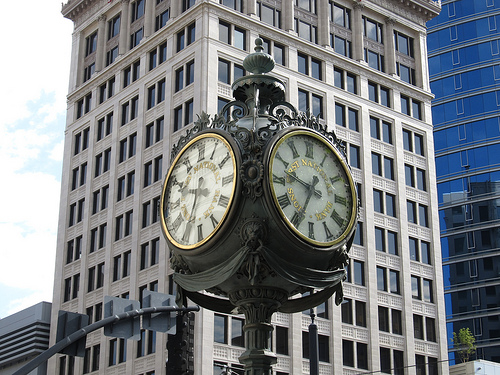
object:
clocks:
[157, 129, 250, 258]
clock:
[260, 124, 365, 271]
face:
[266, 129, 360, 246]